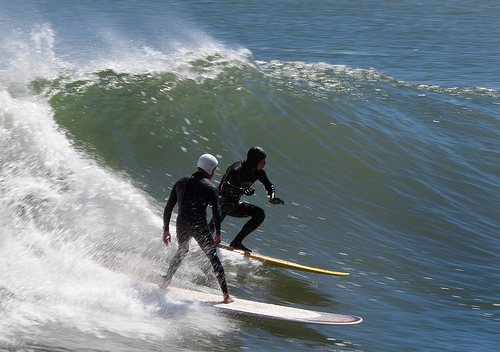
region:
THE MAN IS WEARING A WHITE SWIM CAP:
[193, 147, 222, 189]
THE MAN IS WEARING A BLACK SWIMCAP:
[242, 138, 267, 175]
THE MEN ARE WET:
[142, 131, 287, 306]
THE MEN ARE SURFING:
[159, 120, 289, 325]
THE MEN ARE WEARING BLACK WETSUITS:
[143, 135, 283, 317]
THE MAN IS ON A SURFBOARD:
[153, 145, 237, 301]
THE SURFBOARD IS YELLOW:
[172, 226, 359, 289]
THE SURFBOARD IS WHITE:
[138, 267, 364, 344]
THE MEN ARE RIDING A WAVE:
[152, 138, 287, 323]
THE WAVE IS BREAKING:
[1, 20, 259, 340]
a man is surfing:
[90, 133, 325, 349]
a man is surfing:
[172, 143, 297, 345]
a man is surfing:
[176, 212, 256, 347]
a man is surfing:
[127, 112, 251, 323]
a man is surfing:
[135, 171, 222, 333]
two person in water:
[107, 100, 406, 349]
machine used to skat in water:
[136, 237, 386, 347]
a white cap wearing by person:
[186, 145, 227, 178]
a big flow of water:
[32, 35, 497, 167]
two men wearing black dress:
[93, 80, 328, 350]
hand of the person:
[211, 201, 243, 248]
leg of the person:
[133, 245, 257, 291]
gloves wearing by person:
[267, 187, 282, 205]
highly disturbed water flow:
[11, 126, 218, 338]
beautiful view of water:
[28, 8, 490, 342]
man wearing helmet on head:
[186, 146, 220, 182]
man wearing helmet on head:
[240, 140, 271, 178]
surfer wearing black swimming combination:
[155, 151, 235, 307]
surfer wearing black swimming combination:
[215, 140, 285, 257]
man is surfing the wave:
[160, 151, 233, 313]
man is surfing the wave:
[212, 140, 283, 261]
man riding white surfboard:
[154, 148, 262, 324]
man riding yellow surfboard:
[221, 137, 362, 284]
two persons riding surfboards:
[142, 139, 369, 331]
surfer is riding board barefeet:
[150, 145, 241, 318]